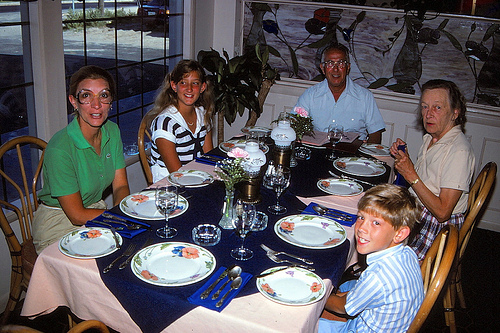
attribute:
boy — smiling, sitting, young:
[314, 184, 424, 332]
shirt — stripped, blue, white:
[343, 241, 425, 333]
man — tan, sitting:
[294, 45, 385, 146]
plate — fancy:
[132, 241, 216, 287]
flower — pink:
[171, 245, 198, 260]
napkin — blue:
[187, 263, 253, 312]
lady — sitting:
[33, 64, 131, 257]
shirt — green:
[38, 116, 127, 207]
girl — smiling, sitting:
[142, 59, 213, 188]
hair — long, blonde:
[142, 57, 218, 134]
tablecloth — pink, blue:
[18, 128, 400, 332]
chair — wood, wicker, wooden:
[1, 135, 49, 323]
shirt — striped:
[149, 101, 214, 167]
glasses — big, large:
[73, 88, 114, 104]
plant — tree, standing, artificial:
[191, 41, 281, 145]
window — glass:
[60, 1, 185, 152]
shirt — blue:
[292, 77, 386, 141]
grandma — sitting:
[390, 77, 475, 267]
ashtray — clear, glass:
[191, 222, 222, 246]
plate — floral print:
[259, 267, 327, 305]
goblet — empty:
[229, 201, 259, 260]